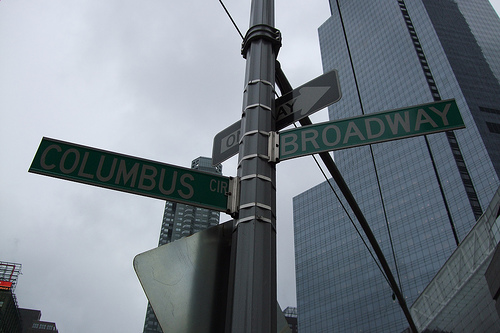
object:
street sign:
[26, 136, 230, 215]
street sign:
[277, 98, 469, 161]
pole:
[229, 1, 284, 332]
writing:
[40, 144, 228, 201]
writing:
[281, 102, 452, 157]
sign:
[235, 78, 275, 169]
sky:
[1, 1, 333, 332]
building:
[292, 1, 498, 333]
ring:
[242, 103, 272, 111]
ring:
[238, 130, 270, 144]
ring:
[238, 153, 270, 168]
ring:
[240, 173, 274, 183]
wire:
[219, 1, 416, 333]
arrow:
[292, 86, 333, 115]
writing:
[226, 82, 334, 153]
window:
[308, 214, 314, 221]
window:
[393, 171, 400, 181]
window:
[409, 150, 417, 159]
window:
[418, 202, 426, 211]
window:
[357, 175, 365, 182]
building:
[142, 156, 225, 332]